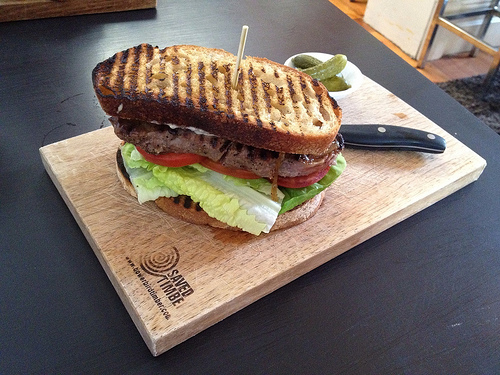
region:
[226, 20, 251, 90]
toothpick in large sandwich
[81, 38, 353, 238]
tall sandwich is assembled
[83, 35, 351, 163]
bread on top is toasted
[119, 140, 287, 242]
lettuce is on sandwich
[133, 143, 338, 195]
sliced tomatoes on sandwich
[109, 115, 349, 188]
cooked steak on sandwich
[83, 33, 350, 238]
whole sandwich on cutting board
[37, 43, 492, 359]
cutting board holding sandwich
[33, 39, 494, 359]
cutting board is wooden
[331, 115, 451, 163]
black handle of utensil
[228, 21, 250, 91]
small wooden skewer in sandwich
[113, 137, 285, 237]
thin light green lettuce slices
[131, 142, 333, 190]
thinly sliced red tomatoes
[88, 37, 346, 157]
grilled piece of white bread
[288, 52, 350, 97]
small green pickles in container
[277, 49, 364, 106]
small circular white bowl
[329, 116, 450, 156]
black and silver knife handle on board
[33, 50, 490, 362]
beige and white rectangular wooden chopping board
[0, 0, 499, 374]
black wooden table with board and sandwich on it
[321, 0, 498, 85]
light brown wooden floor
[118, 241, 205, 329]
The logo on the board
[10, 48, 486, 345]
The board is made of wood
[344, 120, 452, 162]
The black handle of the utensil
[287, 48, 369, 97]
The pickles in the container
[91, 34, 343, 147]
The bread is kind of burned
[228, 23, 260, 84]
The wooden toothpick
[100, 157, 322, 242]
The bottom bun of the sandwich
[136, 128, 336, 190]
The tuna fish in the sandwich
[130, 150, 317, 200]
The tomatoes in the sandwich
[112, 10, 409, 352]
a sandwich on a block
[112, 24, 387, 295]
a sandwich on a wooden blcok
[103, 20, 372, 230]
a sandiwch with toasted bread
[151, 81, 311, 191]
a sandwich with cooked meat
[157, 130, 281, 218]
a sandiwhc iwth lettuce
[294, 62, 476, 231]
a knife on blcok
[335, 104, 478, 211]
a knife on wooden block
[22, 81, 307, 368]
a wooden block on table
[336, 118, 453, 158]
black handle on the cutting board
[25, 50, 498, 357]
wooden cutting board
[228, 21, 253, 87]
skewer in a sandwich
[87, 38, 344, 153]
top bread on a sandwich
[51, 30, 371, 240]
sandwich on the board